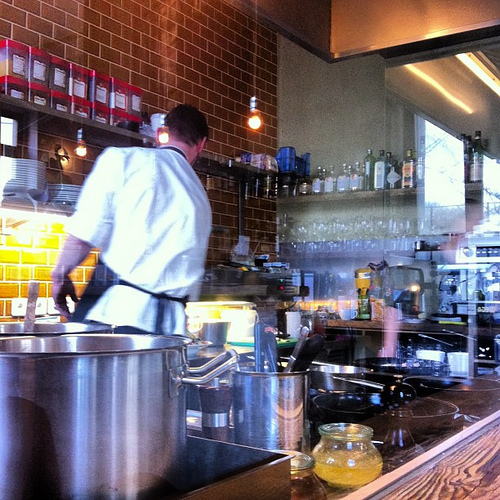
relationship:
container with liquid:
[305, 417, 382, 490] [314, 455, 385, 489]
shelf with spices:
[4, 94, 300, 185] [4, 33, 157, 129]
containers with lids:
[0, 35, 150, 135] [0, 35, 141, 131]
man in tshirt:
[50, 103, 214, 349] [69, 139, 211, 343]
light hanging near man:
[242, 42, 275, 134] [50, 103, 214, 349]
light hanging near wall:
[242, 42, 275, 134] [4, 4, 322, 319]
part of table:
[468, 400, 484, 421] [165, 368, 496, 498]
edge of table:
[392, 445, 437, 473] [165, 368, 496, 498]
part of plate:
[412, 377, 432, 391] [406, 367, 492, 405]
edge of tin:
[263, 410, 279, 426] [231, 356, 309, 470]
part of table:
[248, 465, 283, 484] [165, 368, 496, 498]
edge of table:
[424, 444, 461, 473] [165, 368, 496, 498]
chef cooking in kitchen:
[52, 97, 222, 344] [5, 1, 492, 498]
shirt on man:
[70, 143, 224, 339] [42, 97, 228, 336]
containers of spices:
[3, 35, 151, 134] [2, 32, 142, 131]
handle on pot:
[176, 332, 246, 395] [4, 322, 248, 498]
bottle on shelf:
[296, 146, 415, 196] [279, 187, 421, 207]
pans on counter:
[312, 364, 462, 415] [260, 364, 496, 497]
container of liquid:
[305, 417, 382, 490] [313, 451, 385, 487]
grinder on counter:
[378, 366, 425, 460] [172, 350, 499, 494]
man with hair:
[54, 91, 215, 350] [159, 98, 215, 147]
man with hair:
[50, 103, 214, 349] [159, 98, 215, 147]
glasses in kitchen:
[281, 212, 440, 261] [5, 1, 492, 498]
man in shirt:
[54, 91, 215, 350] [74, 141, 217, 348]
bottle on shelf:
[354, 140, 417, 206] [295, 175, 432, 203]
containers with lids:
[0, 35, 150, 135] [3, 23, 145, 92]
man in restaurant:
[50, 103, 214, 349] [18, 14, 475, 472]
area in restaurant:
[19, 15, 484, 420] [18, 14, 475, 472]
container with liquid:
[305, 417, 382, 490] [300, 404, 359, 498]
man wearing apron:
[50, 103, 214, 349] [68, 231, 218, 319]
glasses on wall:
[281, 212, 432, 260] [295, 152, 431, 259]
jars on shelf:
[328, 151, 410, 211] [300, 168, 410, 215]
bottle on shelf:
[296, 146, 415, 196] [300, 168, 410, 215]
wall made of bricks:
[142, 25, 242, 80] [143, 6, 287, 87]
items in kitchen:
[242, 300, 455, 456] [11, 11, 484, 427]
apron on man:
[75, 265, 125, 305] [86, 121, 190, 317]